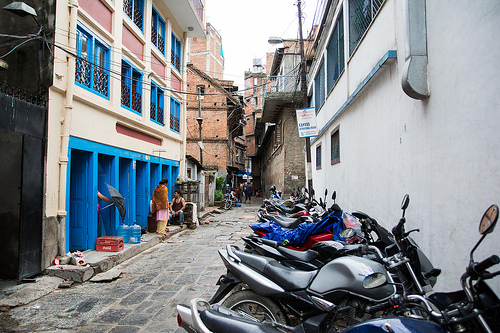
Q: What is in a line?
A: Motorcycles.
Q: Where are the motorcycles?
A: Side of the road.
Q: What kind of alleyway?
A: Rock.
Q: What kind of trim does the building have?
A: Blue.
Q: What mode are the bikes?
A: Parked.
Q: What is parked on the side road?
A: Motorcycles.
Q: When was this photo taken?
A: Daytime.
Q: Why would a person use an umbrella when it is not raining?
A: For shade.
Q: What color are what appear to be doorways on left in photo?
A: Bright blue.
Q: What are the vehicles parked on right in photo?
A: Motorcycles.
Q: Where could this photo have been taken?
A: Alleyway.